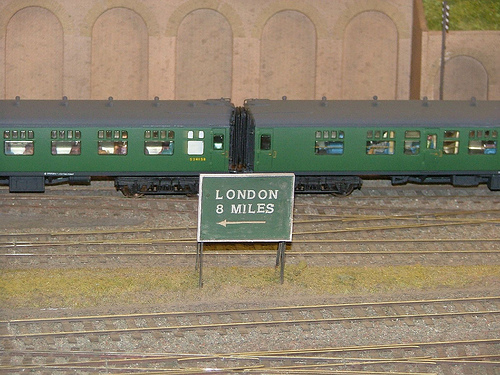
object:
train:
[0, 96, 500, 199]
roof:
[246, 98, 500, 128]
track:
[0, 185, 500, 258]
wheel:
[122, 185, 148, 197]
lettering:
[215, 189, 278, 200]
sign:
[198, 173, 295, 242]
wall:
[0, 1, 411, 102]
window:
[144, 141, 173, 156]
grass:
[0, 263, 497, 301]